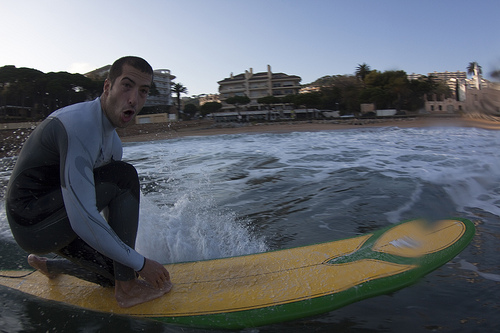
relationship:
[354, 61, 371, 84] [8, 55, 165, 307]
palm tree behind man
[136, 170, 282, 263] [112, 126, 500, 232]
splashing of ocean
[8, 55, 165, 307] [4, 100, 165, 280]
man wearing wetsuit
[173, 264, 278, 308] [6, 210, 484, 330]
water on top of surfboard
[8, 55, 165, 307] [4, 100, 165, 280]
man in wetsuit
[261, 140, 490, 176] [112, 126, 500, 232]
foam in ocean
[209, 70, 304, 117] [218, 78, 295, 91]
building has levels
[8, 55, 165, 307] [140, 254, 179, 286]
man has hand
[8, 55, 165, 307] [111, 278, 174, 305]
man has foot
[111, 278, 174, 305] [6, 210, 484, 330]
foot on top of surfboard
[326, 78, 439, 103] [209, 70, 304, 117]
trees beside house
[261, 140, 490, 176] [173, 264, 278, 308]
foam in water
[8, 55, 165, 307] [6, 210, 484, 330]
man riding surfboard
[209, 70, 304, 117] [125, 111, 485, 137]
house on beach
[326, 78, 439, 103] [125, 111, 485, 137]
trees on beach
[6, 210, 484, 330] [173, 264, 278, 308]
surfboard in water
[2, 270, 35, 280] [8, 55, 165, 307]
cord near man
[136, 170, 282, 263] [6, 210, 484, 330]
splashing near surfboard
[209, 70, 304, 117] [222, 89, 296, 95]
house has balcony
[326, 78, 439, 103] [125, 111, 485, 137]
trees behind beach